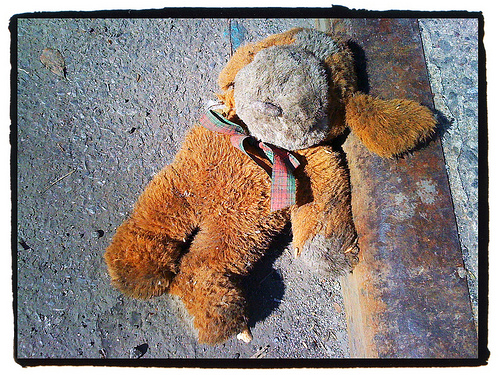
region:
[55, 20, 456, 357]
sombre photo of distressed beaten toy on city ground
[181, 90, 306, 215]
tartan ribbon around neck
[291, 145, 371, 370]
grimy paw pads on muddy legs, beside rusted steel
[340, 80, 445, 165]
one ear, transformed by dust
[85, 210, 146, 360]
two small stones beside+below right foot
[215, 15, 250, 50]
blue chalk - pastel - oilstick beside a lost toy eye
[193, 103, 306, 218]
regardless of the rest, ribbon remains red+bowed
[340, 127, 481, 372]
rust on stell from black to blue to white to red to a rough rough tan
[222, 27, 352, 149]
a grey face once was white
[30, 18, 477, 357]
a bear, a donkey, a horse? all lost, ashes to ashes, & one last leaf in city dirt, upper left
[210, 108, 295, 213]
checkered bow on stuffed bear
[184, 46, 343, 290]
A stuffed animal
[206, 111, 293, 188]
a ribbon on the stuffed animal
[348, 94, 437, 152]
ears on stuffed animal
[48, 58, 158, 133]
The ground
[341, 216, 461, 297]
The curb of the street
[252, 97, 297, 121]
mouth of the stuffed animal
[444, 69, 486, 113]
sidewalk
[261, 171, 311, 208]
green and red ribbon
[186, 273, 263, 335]
feet of stuffed animal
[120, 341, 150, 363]
small rock in street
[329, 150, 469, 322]
the curb is rusty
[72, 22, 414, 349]
this is a brown stuffed animal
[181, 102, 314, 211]
a plaid ribbon around the neck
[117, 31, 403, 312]
the stuffed animal is on the street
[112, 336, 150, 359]
a small pebble on the street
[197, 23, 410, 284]
the stuffed animal is dirty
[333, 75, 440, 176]
the ear is on the curb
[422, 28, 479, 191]
the sidewalk is next to the curb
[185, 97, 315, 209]
the bow is red and green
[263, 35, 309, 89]
the nose is gone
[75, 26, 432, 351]
stuffed animal on ground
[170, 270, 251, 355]
paw of stuffed animal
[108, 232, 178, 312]
paw of stuffed animal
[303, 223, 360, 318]
paw of stuffed animal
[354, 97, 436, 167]
ear of stuffed animal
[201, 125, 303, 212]
plaid bow around neck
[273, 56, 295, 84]
nose of stuffed animal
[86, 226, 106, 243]
rock on black road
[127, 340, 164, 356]
rock on black road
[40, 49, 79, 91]
leaf on black road